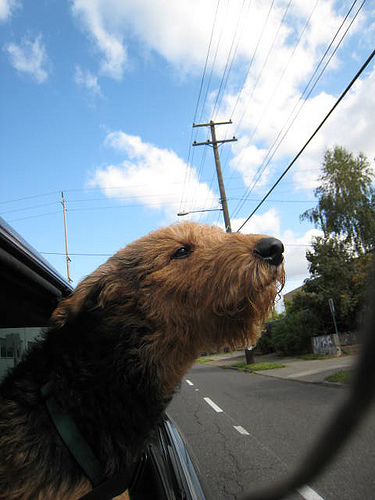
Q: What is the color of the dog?
A: Brown.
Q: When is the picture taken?
A: Daytime.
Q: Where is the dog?
A: Car.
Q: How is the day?
A: Sunny.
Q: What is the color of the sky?
A: Blue.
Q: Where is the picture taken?
A: Inside of car.